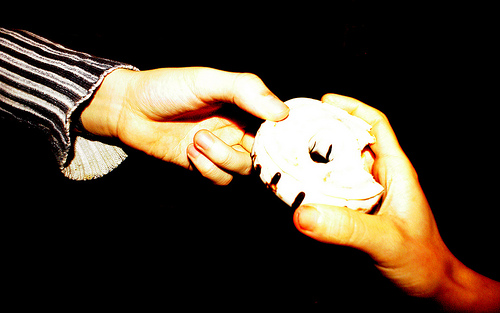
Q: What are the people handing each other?
A: Donut.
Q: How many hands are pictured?
A: Two.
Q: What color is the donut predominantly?
A: White.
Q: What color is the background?
A: Black.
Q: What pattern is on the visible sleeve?
A: Stripes.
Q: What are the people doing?
A: Sharing.